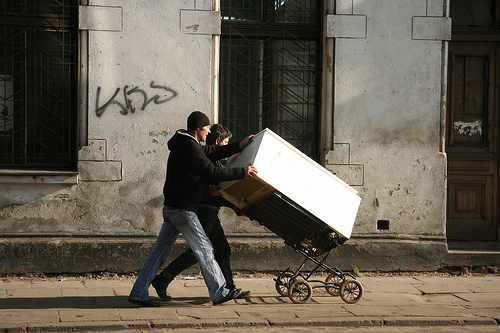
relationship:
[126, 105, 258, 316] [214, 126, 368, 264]
men pushing appliance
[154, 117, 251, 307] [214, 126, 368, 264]
men pushing appliance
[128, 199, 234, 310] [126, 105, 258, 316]
jeans on men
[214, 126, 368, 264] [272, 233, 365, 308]
appliance on cart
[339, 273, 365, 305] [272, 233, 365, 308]
wheels on cart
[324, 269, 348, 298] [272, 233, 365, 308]
wheels on cart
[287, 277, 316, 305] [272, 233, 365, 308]
wheels on cart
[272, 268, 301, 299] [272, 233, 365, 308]
wheels on cart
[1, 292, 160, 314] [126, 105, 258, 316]
shadow of men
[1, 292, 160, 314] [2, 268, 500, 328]
shadow on sidewalk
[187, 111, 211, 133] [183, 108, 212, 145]
hat on head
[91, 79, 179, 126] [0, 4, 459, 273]
paint on wall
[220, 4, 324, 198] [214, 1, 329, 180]
bars on window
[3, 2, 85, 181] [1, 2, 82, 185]
bars on window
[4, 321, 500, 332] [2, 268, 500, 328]
curb on sidewalk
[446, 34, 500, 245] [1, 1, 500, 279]
door on building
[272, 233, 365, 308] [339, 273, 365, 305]
cart has wheels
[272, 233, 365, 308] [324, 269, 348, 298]
cart has wheels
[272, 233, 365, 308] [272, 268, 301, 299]
cart has wheels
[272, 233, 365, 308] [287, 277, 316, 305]
cart has wheels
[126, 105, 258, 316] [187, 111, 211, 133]
men wearing hat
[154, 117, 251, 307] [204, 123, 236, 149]
men has hair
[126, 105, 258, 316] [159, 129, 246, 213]
men has coat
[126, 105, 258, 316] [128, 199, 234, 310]
men has jeans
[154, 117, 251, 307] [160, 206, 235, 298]
men has pants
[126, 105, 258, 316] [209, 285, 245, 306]
men wearing shoes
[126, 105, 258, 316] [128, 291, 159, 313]
men wearing shoes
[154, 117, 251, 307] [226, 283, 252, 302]
men wearing shoes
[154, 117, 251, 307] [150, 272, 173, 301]
men wearing shoes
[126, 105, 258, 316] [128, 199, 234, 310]
men in jeans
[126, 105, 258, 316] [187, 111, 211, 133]
men in hat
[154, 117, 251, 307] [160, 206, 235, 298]
men with pants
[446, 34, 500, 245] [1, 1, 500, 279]
door to building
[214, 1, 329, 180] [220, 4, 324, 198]
window with bars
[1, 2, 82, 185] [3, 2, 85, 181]
window with bars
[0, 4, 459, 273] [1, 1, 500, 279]
wall of building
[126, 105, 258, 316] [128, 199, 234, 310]
men wearing jeans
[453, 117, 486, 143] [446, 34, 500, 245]
paper on door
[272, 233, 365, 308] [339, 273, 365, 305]
cart with wheels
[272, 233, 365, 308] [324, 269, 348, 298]
cart with wheels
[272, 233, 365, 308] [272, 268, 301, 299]
cart with wheels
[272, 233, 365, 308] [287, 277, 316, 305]
cart with wheels